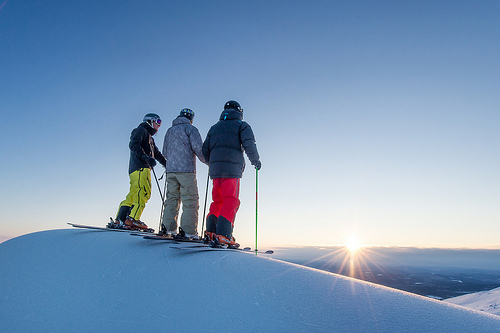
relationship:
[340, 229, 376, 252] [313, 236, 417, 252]
sun shining on horizon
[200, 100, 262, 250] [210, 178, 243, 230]
person with pants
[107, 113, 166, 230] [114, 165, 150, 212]
man wearing pants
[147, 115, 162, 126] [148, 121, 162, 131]
goggles on eyes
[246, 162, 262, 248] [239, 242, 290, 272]
pole in snow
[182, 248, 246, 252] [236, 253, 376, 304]
skis on slope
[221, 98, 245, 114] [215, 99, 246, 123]
hat on head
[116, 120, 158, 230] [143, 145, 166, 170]
man pointing with hand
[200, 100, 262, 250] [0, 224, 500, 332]
person on hill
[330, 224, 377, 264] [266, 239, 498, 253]
sun on horizon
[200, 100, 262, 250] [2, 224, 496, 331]
person on hill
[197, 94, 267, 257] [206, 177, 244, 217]
person has pants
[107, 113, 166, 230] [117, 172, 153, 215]
man wears pants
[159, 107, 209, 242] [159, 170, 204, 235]
person wears pants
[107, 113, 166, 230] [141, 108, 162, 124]
man wears helmet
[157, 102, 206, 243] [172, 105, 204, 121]
person wears helmet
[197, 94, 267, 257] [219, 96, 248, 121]
person wears helmet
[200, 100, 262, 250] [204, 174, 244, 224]
person has pants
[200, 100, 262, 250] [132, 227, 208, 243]
person on snowboard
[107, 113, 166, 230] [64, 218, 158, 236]
man on snowboard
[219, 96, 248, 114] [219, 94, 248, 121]
helmet on head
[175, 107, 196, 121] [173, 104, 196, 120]
helmet on head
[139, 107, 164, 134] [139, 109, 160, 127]
head on helmet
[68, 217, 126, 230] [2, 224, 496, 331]
skis on hill